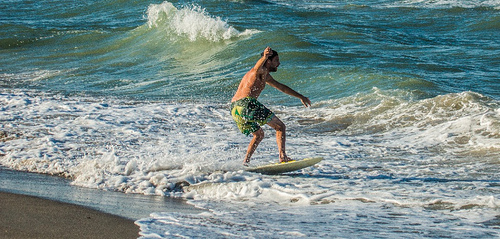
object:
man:
[229, 46, 311, 167]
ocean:
[0, 0, 499, 237]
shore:
[1, 166, 141, 239]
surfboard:
[247, 157, 324, 175]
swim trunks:
[229, 97, 275, 137]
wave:
[105, 2, 329, 87]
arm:
[252, 58, 267, 78]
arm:
[266, 74, 301, 98]